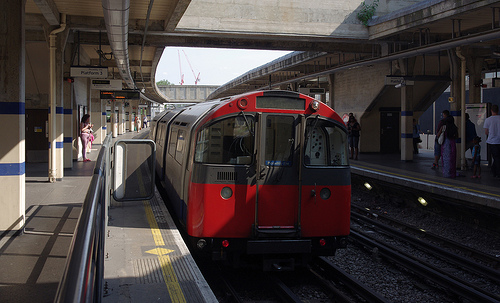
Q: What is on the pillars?
A: Blue stripes.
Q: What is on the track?
A: A train.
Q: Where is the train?
A: At the platform.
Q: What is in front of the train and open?
A: Door.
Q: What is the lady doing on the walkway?
A: Standing.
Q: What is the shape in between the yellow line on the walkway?
A: Diamond.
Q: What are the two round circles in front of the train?
A: Headlight.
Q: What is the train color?
A: Red.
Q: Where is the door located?
A: Front of train.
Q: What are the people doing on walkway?
A: Standing.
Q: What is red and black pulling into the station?
A: A train.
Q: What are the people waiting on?
A: A platform.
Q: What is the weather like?
A: Sunny.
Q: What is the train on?
A: Tracks.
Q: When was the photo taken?
A: Daytime.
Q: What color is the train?
A: Red and gray.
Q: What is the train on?
A: Tracks.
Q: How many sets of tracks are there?
A: Two.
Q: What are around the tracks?
A: Gravel.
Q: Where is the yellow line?
A: Left side of the train.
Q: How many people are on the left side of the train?
A: One.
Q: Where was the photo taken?
A: At a train station.